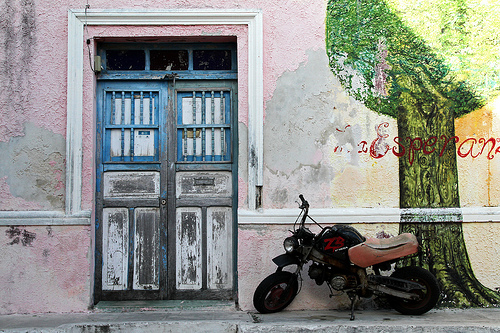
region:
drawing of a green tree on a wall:
[326, 0, 498, 307]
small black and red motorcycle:
[253, 193, 440, 319]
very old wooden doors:
[93, 34, 235, 297]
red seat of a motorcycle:
[348, 233, 416, 266]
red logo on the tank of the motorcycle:
[323, 235, 344, 250]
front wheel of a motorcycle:
[254, 270, 298, 312]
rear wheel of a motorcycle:
[390, 266, 439, 316]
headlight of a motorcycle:
[284, 236, 298, 251]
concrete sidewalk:
[0, 308, 499, 331]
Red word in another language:
[334, 123, 499, 158]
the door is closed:
[92, 60, 242, 312]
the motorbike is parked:
[210, 151, 452, 330]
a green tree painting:
[318, 3, 463, 322]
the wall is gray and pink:
[10, 13, 67, 228]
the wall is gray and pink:
[242, 35, 382, 219]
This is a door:
[108, 41, 260, 270]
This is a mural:
[325, 48, 497, 308]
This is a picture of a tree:
[311, 91, 493, 271]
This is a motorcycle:
[252, 256, 410, 325]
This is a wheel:
[170, 258, 371, 327]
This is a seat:
[325, 194, 437, 269]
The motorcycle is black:
[240, 164, 451, 321]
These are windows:
[56, 39, 228, 98]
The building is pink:
[243, 55, 445, 193]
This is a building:
[247, 84, 355, 205]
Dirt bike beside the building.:
[251, 193, 438, 320]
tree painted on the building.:
[325, 0, 498, 309]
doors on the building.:
[97, 74, 237, 310]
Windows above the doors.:
[100, 44, 235, 74]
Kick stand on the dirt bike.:
[342, 285, 359, 323]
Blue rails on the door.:
[177, 128, 232, 163]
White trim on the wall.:
[1, 203, 94, 235]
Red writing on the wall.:
[332, 119, 498, 167]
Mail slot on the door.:
[191, 175, 216, 187]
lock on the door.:
[159, 196, 166, 206]